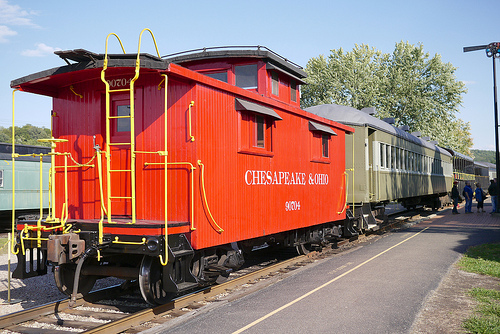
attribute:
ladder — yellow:
[107, 30, 156, 221]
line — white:
[230, 221, 430, 331]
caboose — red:
[43, 54, 414, 287]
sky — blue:
[305, 8, 473, 27]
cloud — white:
[0, 18, 18, 52]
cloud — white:
[1, 6, 42, 28]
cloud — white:
[17, 36, 59, 59]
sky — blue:
[0, 3, 498, 150]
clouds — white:
[3, 5, 42, 40]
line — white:
[271, 246, 398, 310]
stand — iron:
[16, 150, 176, 243]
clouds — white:
[222, 14, 254, 36]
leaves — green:
[316, 47, 402, 122]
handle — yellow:
[164, 100, 217, 149]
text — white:
[240, 164, 333, 189]